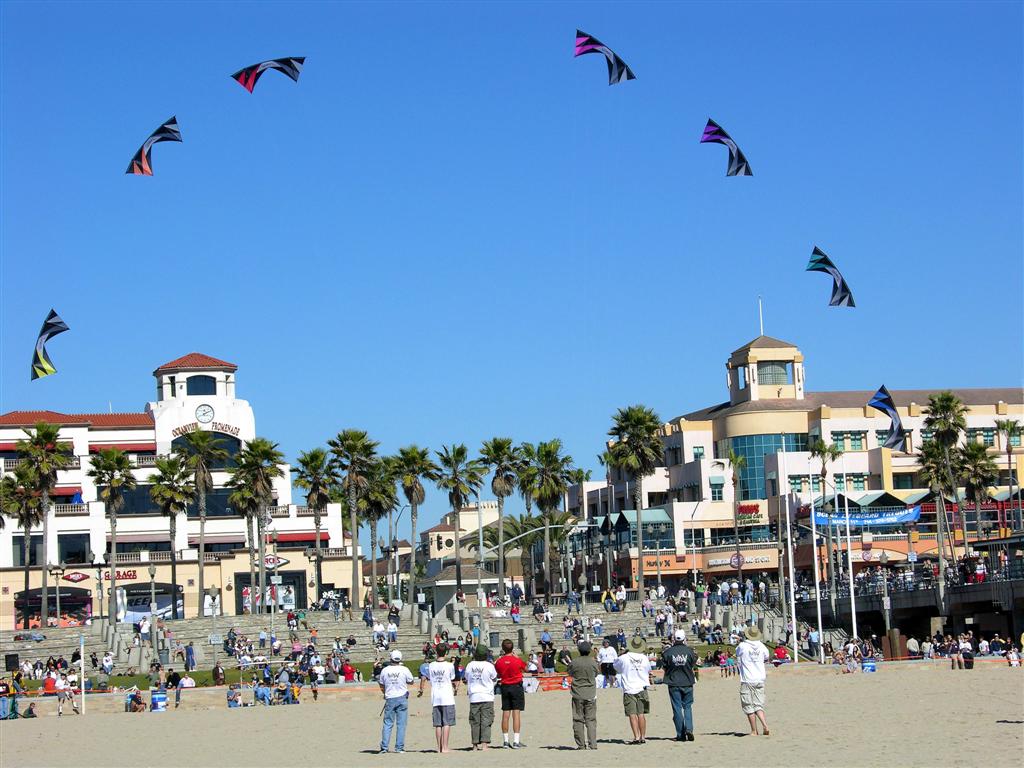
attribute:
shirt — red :
[485, 649, 540, 702]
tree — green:
[211, 430, 274, 513]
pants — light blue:
[375, 677, 414, 760]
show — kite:
[67, 94, 973, 710]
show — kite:
[26, 74, 966, 733]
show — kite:
[84, 42, 890, 743]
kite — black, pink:
[119, 111, 189, 187]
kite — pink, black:
[225, 55, 308, 103]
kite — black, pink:
[568, 24, 640, 94]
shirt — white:
[732, 640, 769, 688]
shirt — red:
[490, 633, 521, 688]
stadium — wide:
[95, 549, 668, 705]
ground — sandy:
[797, 706, 973, 752]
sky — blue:
[316, 184, 643, 487]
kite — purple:
[681, 155, 785, 171]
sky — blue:
[387, 205, 584, 266]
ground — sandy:
[875, 678, 981, 756]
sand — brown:
[827, 696, 1003, 763]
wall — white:
[158, 465, 219, 580]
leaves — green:
[367, 481, 389, 518]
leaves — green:
[627, 425, 653, 462]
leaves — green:
[925, 417, 951, 461]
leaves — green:
[32, 436, 58, 484]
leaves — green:
[404, 447, 418, 473]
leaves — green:
[311, 458, 333, 495]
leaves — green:
[620, 417, 649, 450]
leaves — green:
[445, 458, 474, 498]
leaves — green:
[236, 481, 262, 514]